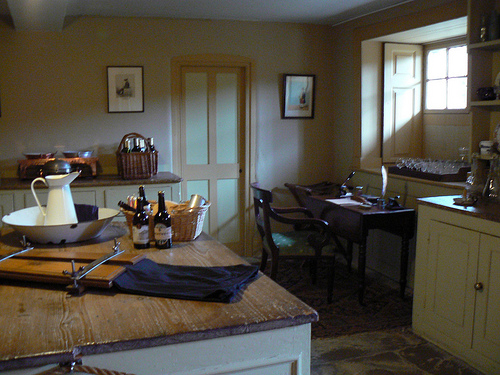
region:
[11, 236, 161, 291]
a wooden cutting board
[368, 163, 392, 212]
a feather quill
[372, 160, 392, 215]
quill in a bottle of ink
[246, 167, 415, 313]
an old wooden desk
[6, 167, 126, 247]
a white water pitcher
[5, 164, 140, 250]
a water pitcher in a basin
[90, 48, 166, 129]
a framed photograph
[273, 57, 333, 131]
a picture in a black frame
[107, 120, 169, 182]
a basket of wine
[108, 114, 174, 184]
wine bottles in a basket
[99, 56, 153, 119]
Framed picture on a wall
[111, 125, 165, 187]
A basket full of bottles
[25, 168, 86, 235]
A white metal pitcher in a bowl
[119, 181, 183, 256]
3 bottles on a wooden table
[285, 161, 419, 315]
Wooden table in a kitchen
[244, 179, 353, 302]
Wooden chair at a table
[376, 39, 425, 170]
Wooden shutter on kitchen window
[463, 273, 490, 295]
Metal knob on cabinet door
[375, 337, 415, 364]
Floral rug on kitchen floor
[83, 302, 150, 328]
Wooden kitchen table top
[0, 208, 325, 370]
A kitchen island.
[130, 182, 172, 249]
Dark bottles with white labels.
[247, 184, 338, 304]
A dark wooden chair with a cushion.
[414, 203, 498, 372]
White cabinets.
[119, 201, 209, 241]
A light brown wicker basket.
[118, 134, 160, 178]
A dark brown woven basket.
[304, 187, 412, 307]
A dark brown table.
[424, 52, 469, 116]
A small window.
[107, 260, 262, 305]
A black cloth.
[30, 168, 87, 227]
A white pitcher.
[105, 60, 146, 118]
Picture of person sitting.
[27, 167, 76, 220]
White pitcher on table.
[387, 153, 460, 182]
Dark tray filled with glasses.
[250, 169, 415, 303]
Brown chair and table.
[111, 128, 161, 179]
Dark brown basket of bottles.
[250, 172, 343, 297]
Dark brown chair with green cushion.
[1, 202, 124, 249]
White water basin on table.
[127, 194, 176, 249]
Two dark bottles on table.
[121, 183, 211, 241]
Light brown basket near basin.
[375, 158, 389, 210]
Feather pen on dark table.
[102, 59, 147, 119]
picture on the wall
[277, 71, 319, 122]
picture opposite other picture on wall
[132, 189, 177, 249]
two bottles beside each other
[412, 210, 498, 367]
cabinet doors underneath counter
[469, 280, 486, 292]
knob to open cabinet door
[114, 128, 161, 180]
basket with several bottles in it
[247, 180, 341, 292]
wooden chair at table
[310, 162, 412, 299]
table with several items on it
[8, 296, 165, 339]
wooden counter top to center island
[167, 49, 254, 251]
door to other room or pantry